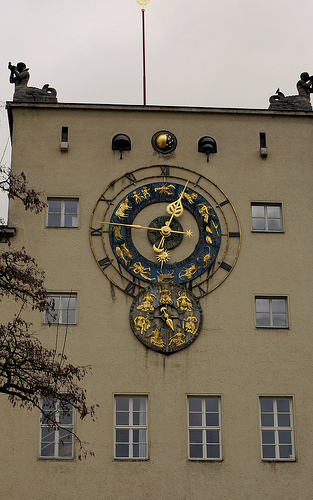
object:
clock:
[88, 163, 243, 354]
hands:
[92, 175, 200, 262]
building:
[2, 99, 310, 498]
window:
[249, 202, 281, 232]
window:
[114, 393, 148, 461]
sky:
[153, 4, 311, 67]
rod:
[142, 11, 146, 106]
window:
[44, 195, 80, 225]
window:
[255, 293, 289, 328]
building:
[51, 101, 296, 285]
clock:
[88, 164, 242, 302]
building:
[61, 73, 300, 380]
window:
[41, 290, 76, 324]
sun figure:
[155, 246, 171, 264]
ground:
[237, 59, 274, 90]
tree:
[1, 132, 101, 461]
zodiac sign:
[108, 183, 222, 285]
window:
[39, 390, 75, 458]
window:
[187, 394, 223, 463]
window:
[259, 394, 295, 462]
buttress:
[260, 131, 268, 158]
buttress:
[60, 126, 70, 151]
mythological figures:
[128, 282, 204, 353]